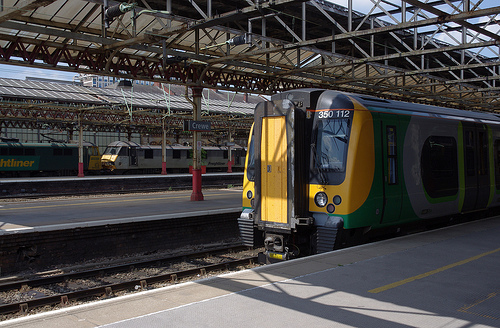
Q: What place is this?
A: It is a station.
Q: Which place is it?
A: It is a station.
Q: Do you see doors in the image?
A: Yes, there is a door.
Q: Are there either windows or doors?
A: Yes, there is a door.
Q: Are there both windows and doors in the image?
A: Yes, there are both a door and a window.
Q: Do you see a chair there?
A: No, there are no chairs.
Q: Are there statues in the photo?
A: No, there are no statues.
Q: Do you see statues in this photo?
A: No, there are no statues.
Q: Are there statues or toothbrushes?
A: No, there are no statues or toothbrushes.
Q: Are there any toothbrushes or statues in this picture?
A: No, there are no statues or toothbrushes.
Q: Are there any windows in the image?
A: Yes, there is a window.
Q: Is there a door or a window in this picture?
A: Yes, there is a window.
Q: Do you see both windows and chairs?
A: No, there is a window but no chairs.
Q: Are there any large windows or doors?
A: Yes, there is a large window.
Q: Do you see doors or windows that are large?
A: Yes, the window is large.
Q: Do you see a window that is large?
A: Yes, there is a window that is large.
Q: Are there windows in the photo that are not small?
A: Yes, there is a large window.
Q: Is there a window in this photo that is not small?
A: Yes, there is a large window.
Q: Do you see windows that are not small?
A: Yes, there is a large window.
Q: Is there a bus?
A: No, there are no buses.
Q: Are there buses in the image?
A: No, there are no buses.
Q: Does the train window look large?
A: Yes, the window is large.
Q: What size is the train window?
A: The window is large.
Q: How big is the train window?
A: The window is large.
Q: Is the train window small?
A: No, the window is large.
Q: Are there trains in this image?
A: Yes, there is a train.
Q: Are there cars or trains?
A: Yes, there is a train.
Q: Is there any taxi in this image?
A: No, there are no taxis.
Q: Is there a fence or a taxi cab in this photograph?
A: No, there are no taxis or fences.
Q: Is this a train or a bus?
A: This is a train.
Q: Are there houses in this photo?
A: No, there are no houses.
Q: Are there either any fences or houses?
A: No, there are no houses or fences.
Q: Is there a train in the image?
A: Yes, there is a train.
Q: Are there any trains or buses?
A: Yes, there is a train.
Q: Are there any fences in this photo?
A: No, there are no fences.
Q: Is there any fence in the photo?
A: No, there are no fences.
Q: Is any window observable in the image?
A: Yes, there is a window.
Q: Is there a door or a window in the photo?
A: Yes, there is a window.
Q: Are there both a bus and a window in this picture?
A: No, there is a window but no buses.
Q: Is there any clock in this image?
A: No, there are no clocks.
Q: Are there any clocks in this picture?
A: No, there are no clocks.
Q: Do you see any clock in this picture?
A: No, there are no clocks.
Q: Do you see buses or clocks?
A: No, there are no clocks or buses.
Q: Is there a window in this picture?
A: Yes, there is a window.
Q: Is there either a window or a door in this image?
A: Yes, there is a window.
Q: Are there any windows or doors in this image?
A: Yes, there is a window.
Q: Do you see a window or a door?
A: Yes, there is a window.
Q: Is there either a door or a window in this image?
A: Yes, there is a window.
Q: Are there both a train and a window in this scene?
A: Yes, there are both a window and a train.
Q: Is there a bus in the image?
A: No, there are no buses.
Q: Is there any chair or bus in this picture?
A: No, there are no buses or chairs.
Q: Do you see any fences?
A: No, there are no fences.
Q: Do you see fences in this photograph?
A: No, there are no fences.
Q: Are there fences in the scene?
A: No, there are no fences.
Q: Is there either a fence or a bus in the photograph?
A: No, there are no fences or buses.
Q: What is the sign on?
A: The sign is on the pole.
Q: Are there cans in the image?
A: No, there are no cans.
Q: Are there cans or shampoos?
A: No, there are no cans or shampoos.